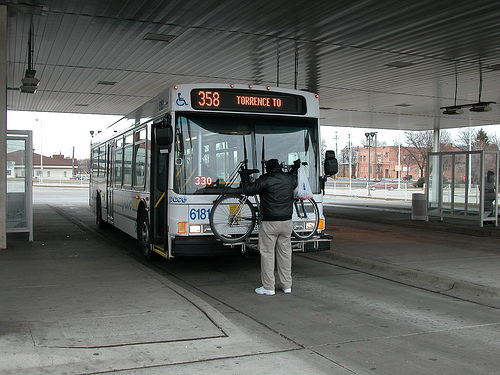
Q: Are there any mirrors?
A: Yes, there is a mirror.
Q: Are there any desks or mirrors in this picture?
A: Yes, there is a mirror.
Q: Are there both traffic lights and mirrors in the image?
A: No, there is a mirror but no traffic lights.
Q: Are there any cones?
A: No, there are no cones.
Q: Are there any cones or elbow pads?
A: No, there are no cones or elbow pads.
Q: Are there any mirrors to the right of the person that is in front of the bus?
A: Yes, there is a mirror to the right of the person.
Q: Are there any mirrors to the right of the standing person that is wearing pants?
A: Yes, there is a mirror to the right of the person.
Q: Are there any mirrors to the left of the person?
A: No, the mirror is to the right of the person.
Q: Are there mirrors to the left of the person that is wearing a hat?
A: No, the mirror is to the right of the person.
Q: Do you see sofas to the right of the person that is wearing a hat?
A: No, there is a mirror to the right of the person.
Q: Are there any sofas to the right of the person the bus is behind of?
A: No, there is a mirror to the right of the person.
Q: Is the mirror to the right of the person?
A: Yes, the mirror is to the right of the person.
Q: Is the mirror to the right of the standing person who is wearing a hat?
A: Yes, the mirror is to the right of the person.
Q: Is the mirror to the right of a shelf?
A: No, the mirror is to the right of the person.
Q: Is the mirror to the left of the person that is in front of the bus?
A: No, the mirror is to the right of the person.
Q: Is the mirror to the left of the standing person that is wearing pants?
A: No, the mirror is to the right of the person.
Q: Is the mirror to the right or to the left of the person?
A: The mirror is to the right of the person.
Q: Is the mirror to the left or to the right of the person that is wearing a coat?
A: The mirror is to the right of the person.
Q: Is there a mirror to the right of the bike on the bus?
A: Yes, there is a mirror to the right of the bike.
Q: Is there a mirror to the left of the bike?
A: No, the mirror is to the right of the bike.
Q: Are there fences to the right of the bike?
A: No, there is a mirror to the right of the bike.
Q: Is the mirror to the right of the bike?
A: Yes, the mirror is to the right of the bike.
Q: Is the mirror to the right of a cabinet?
A: No, the mirror is to the right of the bike.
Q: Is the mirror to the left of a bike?
A: No, the mirror is to the right of a bike.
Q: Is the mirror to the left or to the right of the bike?
A: The mirror is to the right of the bike.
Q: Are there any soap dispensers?
A: No, there are no soap dispensers.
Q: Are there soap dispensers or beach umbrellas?
A: No, there are no soap dispensers or beach umbrellas.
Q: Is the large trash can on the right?
A: Yes, the trash can is on the right of the image.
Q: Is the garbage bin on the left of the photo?
A: No, the garbage bin is on the right of the image.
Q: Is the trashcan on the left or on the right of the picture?
A: The trashcan is on the right of the image.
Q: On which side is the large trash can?
A: The trash can is on the right of the image.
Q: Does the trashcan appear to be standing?
A: Yes, the trashcan is standing.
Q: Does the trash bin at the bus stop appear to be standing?
A: Yes, the trash bin is standing.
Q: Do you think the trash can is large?
A: Yes, the trash can is large.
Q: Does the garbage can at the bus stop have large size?
A: Yes, the garbage bin is large.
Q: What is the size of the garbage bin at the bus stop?
A: The garbage bin is large.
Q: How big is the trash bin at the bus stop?
A: The garbage bin is large.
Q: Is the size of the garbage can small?
A: No, the garbage can is large.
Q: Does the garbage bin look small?
A: No, the garbage bin is large.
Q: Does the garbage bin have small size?
A: No, the garbage bin is large.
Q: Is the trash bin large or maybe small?
A: The trash bin is large.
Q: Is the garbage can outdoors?
A: Yes, the garbage can is outdoors.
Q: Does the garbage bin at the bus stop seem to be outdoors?
A: Yes, the trash can is outdoors.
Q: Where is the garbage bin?
A: The garbage bin is at the bus stop.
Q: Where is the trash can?
A: The garbage bin is at the bus stop.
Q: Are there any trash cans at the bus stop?
A: Yes, there is a trash can at the bus stop.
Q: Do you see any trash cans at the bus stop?
A: Yes, there is a trash can at the bus stop.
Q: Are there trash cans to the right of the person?
A: Yes, there is a trash can to the right of the person.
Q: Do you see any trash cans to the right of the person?
A: Yes, there is a trash can to the right of the person.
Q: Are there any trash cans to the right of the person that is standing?
A: Yes, there is a trash can to the right of the person.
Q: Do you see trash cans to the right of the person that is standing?
A: Yes, there is a trash can to the right of the person.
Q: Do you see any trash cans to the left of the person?
A: No, the trash can is to the right of the person.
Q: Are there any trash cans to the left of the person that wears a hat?
A: No, the trash can is to the right of the person.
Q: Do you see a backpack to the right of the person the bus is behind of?
A: No, there is a trash can to the right of the person.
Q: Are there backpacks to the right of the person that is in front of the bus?
A: No, there is a trash can to the right of the person.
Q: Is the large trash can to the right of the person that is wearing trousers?
A: Yes, the trashcan is to the right of the person.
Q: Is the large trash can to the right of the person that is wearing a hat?
A: Yes, the trashcan is to the right of the person.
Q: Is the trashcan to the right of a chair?
A: No, the trashcan is to the right of the person.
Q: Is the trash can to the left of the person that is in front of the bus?
A: No, the trash can is to the right of the person.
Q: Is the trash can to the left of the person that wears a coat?
A: No, the trash can is to the right of the person.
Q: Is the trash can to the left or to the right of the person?
A: The trash can is to the right of the person.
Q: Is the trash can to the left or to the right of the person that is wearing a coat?
A: The trash can is to the right of the person.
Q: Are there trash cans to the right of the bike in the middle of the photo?
A: Yes, there is a trash can to the right of the bike.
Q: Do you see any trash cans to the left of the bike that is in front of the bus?
A: No, the trash can is to the right of the bike.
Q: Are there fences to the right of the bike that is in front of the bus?
A: No, there is a trash can to the right of the bike.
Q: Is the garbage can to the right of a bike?
A: Yes, the garbage can is to the right of a bike.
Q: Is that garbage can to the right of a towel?
A: No, the garbage can is to the right of a bike.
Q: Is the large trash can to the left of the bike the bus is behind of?
A: No, the trash can is to the right of the bike.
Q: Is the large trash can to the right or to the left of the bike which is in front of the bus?
A: The trash can is to the right of the bike.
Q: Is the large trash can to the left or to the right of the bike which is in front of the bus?
A: The trash can is to the right of the bike.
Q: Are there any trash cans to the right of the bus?
A: Yes, there is a trash can to the right of the bus.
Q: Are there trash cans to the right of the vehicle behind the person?
A: Yes, there is a trash can to the right of the bus.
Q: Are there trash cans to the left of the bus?
A: No, the trash can is to the right of the bus.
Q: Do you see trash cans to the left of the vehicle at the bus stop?
A: No, the trash can is to the right of the bus.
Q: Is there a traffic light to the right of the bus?
A: No, there is a trash can to the right of the bus.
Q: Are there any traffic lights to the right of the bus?
A: No, there is a trash can to the right of the bus.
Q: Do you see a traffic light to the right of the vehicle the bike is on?
A: No, there is a trash can to the right of the bus.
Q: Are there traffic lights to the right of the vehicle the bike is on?
A: No, there is a trash can to the right of the bus.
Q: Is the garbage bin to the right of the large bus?
A: Yes, the garbage bin is to the right of the bus.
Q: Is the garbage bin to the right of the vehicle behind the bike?
A: Yes, the garbage bin is to the right of the bus.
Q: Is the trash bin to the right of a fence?
A: No, the trash bin is to the right of the bus.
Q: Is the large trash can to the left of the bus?
A: No, the trash bin is to the right of the bus.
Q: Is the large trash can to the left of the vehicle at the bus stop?
A: No, the trash bin is to the right of the bus.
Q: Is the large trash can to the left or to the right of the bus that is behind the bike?
A: The trash bin is to the right of the bus.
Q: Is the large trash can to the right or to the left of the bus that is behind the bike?
A: The trash bin is to the right of the bus.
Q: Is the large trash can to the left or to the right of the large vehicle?
A: The trash bin is to the right of the bus.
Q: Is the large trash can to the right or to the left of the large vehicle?
A: The trash bin is to the right of the bus.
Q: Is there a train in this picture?
A: No, there are no trains.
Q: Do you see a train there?
A: No, there are no trains.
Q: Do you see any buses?
A: Yes, there is a bus.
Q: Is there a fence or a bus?
A: Yes, there is a bus.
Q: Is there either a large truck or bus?
A: Yes, there is a large bus.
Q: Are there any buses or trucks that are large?
A: Yes, the bus is large.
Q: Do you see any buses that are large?
A: Yes, there is a large bus.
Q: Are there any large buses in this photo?
A: Yes, there is a large bus.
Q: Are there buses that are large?
A: Yes, there is a bus that is large.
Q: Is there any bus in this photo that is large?
A: Yes, there is a bus that is large.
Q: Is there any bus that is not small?
A: Yes, there is a large bus.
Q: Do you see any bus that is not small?
A: Yes, there is a large bus.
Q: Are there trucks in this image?
A: No, there are no trucks.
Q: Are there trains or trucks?
A: No, there are no trucks or trains.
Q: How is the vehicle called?
A: The vehicle is a bus.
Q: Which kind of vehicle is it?
A: The vehicle is a bus.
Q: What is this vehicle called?
A: This is a bus.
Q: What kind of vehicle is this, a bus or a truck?
A: This is a bus.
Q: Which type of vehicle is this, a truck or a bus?
A: This is a bus.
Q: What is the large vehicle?
A: The vehicle is a bus.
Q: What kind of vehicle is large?
A: The vehicle is a bus.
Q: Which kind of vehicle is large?
A: The vehicle is a bus.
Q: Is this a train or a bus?
A: This is a bus.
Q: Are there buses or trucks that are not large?
A: No, there is a bus but it is large.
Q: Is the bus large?
A: Yes, the bus is large.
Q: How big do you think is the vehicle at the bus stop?
A: The bus is large.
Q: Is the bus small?
A: No, the bus is large.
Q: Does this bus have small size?
A: No, the bus is large.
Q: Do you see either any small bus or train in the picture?
A: No, there is a bus but it is large.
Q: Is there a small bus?
A: No, there is a bus but it is large.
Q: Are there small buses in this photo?
A: No, there is a bus but it is large.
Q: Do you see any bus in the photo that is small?
A: No, there is a bus but it is large.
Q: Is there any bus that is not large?
A: No, there is a bus but it is large.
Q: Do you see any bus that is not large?
A: No, there is a bus but it is large.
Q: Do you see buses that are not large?
A: No, there is a bus but it is large.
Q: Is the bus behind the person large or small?
A: The bus is large.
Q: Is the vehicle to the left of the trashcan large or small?
A: The bus is large.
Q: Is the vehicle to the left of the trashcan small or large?
A: The bus is large.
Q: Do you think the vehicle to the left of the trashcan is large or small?
A: The bus is large.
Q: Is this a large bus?
A: Yes, this is a large bus.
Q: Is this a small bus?
A: No, this is a large bus.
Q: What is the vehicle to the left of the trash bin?
A: The vehicle is a bus.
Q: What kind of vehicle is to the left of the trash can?
A: The vehicle is a bus.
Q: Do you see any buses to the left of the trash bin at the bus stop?
A: Yes, there is a bus to the left of the garbage bin.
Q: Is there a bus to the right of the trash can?
A: No, the bus is to the left of the trash can.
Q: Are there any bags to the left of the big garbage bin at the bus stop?
A: No, there is a bus to the left of the trash can.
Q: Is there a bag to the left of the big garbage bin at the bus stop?
A: No, there is a bus to the left of the trash can.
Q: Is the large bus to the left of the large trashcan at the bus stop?
A: Yes, the bus is to the left of the garbage can.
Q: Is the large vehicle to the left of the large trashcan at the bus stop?
A: Yes, the bus is to the left of the garbage can.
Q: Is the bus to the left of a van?
A: No, the bus is to the left of the garbage can.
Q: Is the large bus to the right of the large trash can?
A: No, the bus is to the left of the garbage bin.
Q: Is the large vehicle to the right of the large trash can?
A: No, the bus is to the left of the garbage bin.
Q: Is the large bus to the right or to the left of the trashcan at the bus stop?
A: The bus is to the left of the garbage can.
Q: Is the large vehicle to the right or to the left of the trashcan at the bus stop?
A: The bus is to the left of the garbage can.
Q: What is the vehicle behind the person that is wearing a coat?
A: The vehicle is a bus.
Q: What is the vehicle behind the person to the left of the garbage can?
A: The vehicle is a bus.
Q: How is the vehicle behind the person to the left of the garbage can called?
A: The vehicle is a bus.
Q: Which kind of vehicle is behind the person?
A: The vehicle is a bus.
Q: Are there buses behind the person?
A: Yes, there is a bus behind the person.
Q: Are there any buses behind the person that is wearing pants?
A: Yes, there is a bus behind the person.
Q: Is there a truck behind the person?
A: No, there is a bus behind the person.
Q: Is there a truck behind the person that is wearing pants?
A: No, there is a bus behind the person.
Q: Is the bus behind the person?
A: Yes, the bus is behind the person.